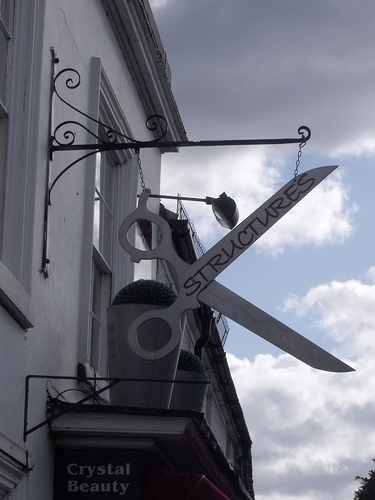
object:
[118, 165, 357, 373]
scissors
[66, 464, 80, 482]
words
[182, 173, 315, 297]
font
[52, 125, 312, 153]
pole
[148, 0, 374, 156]
clouds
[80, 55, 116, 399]
window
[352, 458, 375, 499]
tree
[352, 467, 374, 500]
leaves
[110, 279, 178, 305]
plant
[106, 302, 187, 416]
pot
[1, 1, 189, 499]
building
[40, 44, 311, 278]
sign hanger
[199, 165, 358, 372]
blades open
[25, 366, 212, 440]
sign holder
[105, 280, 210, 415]
two cups of slushies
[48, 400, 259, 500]
ledge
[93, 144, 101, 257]
light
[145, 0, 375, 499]
sky